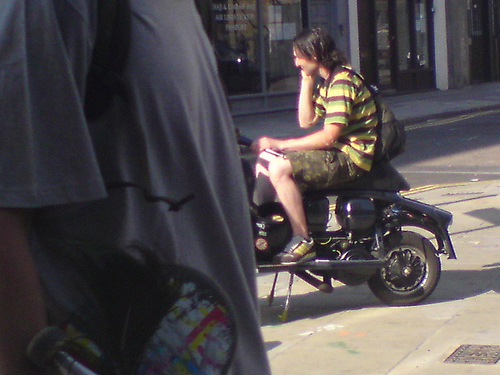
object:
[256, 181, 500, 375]
pavement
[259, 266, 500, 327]
shadow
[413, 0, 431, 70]
store window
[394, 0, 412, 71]
store window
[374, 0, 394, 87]
store window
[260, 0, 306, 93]
store window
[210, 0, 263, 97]
store window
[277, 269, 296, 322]
kick stand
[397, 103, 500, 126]
sidewalk curb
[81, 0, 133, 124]
backpack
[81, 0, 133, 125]
strap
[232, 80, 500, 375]
ground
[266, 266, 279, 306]
kickstands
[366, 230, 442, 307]
tire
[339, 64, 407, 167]
backpack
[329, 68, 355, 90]
shoulders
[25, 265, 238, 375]
skateboard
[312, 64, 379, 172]
shirt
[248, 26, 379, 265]
male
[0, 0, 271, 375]
gray shirt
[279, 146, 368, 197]
shorts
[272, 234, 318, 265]
tennis shoe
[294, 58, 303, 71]
cellphone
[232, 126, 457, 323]
motorbike